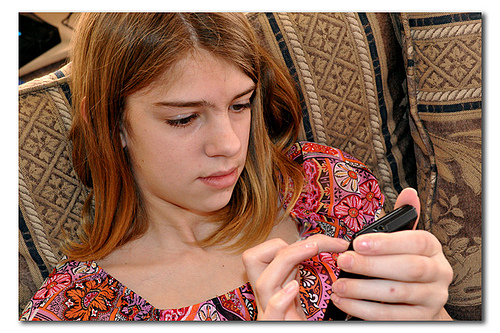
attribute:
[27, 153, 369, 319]
shirt — multi colored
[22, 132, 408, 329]
shirt — multicolored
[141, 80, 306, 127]
eyebrows — growing together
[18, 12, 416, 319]
pillow — brown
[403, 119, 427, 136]
ground — black, white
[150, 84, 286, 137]
eyes — brown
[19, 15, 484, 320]
hair — medium length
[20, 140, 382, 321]
dress — colorful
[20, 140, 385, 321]
shirt — pink, orange, pink and orange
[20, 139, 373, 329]
orange shirt — orange 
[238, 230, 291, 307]
finger — crooked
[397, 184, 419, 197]
thumb nail — well groomed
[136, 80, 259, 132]
eyes — dark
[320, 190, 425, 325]
phone — black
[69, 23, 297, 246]
hair — parted 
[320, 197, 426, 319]
object — black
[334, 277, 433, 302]
ring finger — left ring 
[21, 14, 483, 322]
couch — tan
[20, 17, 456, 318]
girl — texting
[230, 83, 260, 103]
eyebrow — thick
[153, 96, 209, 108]
eyebrow — thick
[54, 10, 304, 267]
hair — brown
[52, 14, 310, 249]
hair — REd , brown